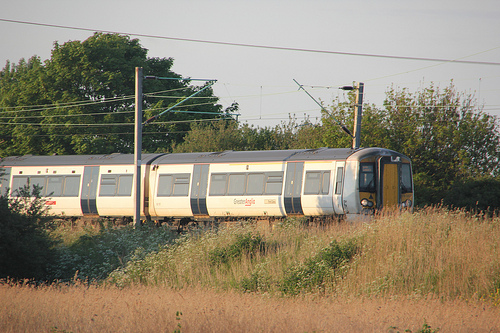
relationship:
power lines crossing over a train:
[0, 18, 499, 137] [0, 146, 417, 223]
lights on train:
[401, 197, 413, 204] [1, 146, 417, 215]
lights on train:
[360, 196, 376, 208] [1, 146, 417, 215]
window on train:
[261, 174, 283, 194] [2, 151, 412, 221]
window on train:
[250, 174, 267, 193] [2, 151, 412, 221]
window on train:
[221, 171, 244, 198] [2, 151, 412, 221]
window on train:
[209, 173, 231, 193] [2, 151, 412, 221]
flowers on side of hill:
[43, 214, 221, 294] [3, 217, 499, 304]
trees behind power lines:
[0, 29, 244, 155] [0, 18, 499, 137]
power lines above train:
[0, 18, 499, 137] [0, 146, 417, 223]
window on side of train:
[155, 170, 193, 202] [0, 146, 417, 223]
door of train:
[188, 159, 213, 222] [0, 126, 422, 224]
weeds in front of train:
[22, 213, 465, 330] [20, 140, 430, 205]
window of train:
[303, 170, 330, 197] [0, 146, 417, 223]